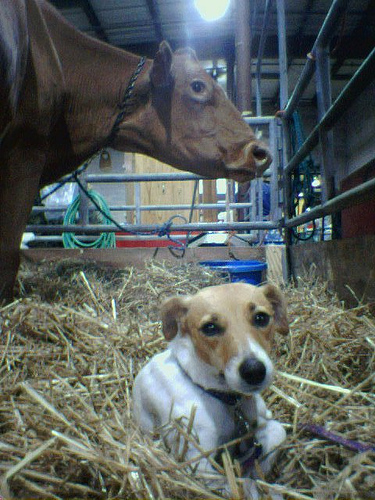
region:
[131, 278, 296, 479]
dog is laying on straw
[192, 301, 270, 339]
dog has black eyes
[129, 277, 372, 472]
dog has purple leash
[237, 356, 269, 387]
dog has black nose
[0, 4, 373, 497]
cow is behind the dog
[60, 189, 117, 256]
green hose on railing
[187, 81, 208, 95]
cow's eye is black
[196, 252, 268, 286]
blue bucket near straw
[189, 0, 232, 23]
light shining on ceiling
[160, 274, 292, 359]
part of dog's head is brown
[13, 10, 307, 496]
two animals are in this pen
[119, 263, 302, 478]
one of the animals is a little dog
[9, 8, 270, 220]
the other animal in the pen is a cow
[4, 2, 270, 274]
the cow is a reddish brown in color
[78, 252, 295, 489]
the little dog is white and light brown in color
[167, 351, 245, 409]
the dog wears a collar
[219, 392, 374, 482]
the dog has a leash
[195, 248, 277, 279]
a blue bucket is in the pen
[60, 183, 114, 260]
a hose hangs in the background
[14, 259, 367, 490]
the pen floor is covered in straw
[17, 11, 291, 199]
this is a cow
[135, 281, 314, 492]
this is a dog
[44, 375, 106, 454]
this is a stuck of hay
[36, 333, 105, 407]
this is a stuck of hay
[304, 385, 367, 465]
this is a stuck of hay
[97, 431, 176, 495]
this is a stuck of hay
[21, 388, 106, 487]
this is a stuck of hay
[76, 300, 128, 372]
this is a stuck of hay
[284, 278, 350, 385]
this is a stuck of hay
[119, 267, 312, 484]
Tan and white puppy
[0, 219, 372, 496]
Puppy lying in the hay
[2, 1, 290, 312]
Brown cow in barn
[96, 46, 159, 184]
Golden bell around cow's neck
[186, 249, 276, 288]
Blue container for water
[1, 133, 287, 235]
Fencing around the animals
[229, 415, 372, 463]
Purple leash holding the dog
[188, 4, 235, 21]
Bright light on the ceiling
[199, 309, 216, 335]
the dog's left eye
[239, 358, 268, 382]
the dog's brown snout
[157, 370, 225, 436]
the dog's white body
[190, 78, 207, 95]
the cow's eye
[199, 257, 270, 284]
a blue bucket in the distance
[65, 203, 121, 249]
a green rope in the background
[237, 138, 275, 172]
the cow's big snout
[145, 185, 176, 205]
a brown door in the background